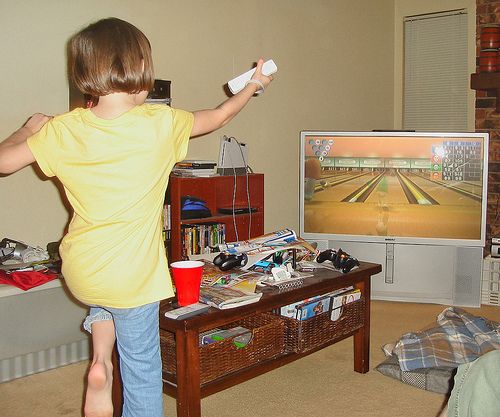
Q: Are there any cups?
A: Yes, there is a cup.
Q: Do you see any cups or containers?
A: Yes, there is a cup.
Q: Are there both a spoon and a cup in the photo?
A: No, there is a cup but no spoons.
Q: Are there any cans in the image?
A: No, there are no cans.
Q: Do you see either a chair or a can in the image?
A: No, there are no cans or chairs.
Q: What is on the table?
A: The cup is on the table.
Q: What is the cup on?
A: The cup is on the table.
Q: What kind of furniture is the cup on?
A: The cup is on the table.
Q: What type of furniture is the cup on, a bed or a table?
A: The cup is on a table.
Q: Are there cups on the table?
A: Yes, there is a cup on the table.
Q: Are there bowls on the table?
A: No, there is a cup on the table.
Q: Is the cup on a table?
A: Yes, the cup is on a table.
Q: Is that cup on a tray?
A: No, the cup is on a table.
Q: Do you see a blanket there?
A: Yes, there is a blanket.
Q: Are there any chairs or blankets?
A: Yes, there is a blanket.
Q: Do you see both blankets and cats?
A: No, there is a blanket but no cats.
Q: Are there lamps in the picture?
A: No, there are no lamps.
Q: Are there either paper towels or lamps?
A: No, there are no lamps or paper towels.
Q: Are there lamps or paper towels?
A: No, there are no lamps or paper towels.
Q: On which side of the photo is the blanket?
A: The blanket is on the right of the image.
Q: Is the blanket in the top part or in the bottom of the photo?
A: The blanket is in the bottom of the image.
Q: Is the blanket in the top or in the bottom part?
A: The blanket is in the bottom of the image.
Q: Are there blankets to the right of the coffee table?
A: Yes, there is a blanket to the right of the coffee table.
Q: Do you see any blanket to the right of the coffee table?
A: Yes, there is a blanket to the right of the coffee table.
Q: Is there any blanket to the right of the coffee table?
A: Yes, there is a blanket to the right of the coffee table.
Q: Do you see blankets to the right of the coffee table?
A: Yes, there is a blanket to the right of the coffee table.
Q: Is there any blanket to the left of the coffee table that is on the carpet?
A: No, the blanket is to the right of the coffee table.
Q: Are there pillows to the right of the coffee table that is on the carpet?
A: No, there is a blanket to the right of the coffee table.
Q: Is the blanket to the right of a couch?
A: No, the blanket is to the right of a coffee table.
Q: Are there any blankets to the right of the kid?
A: Yes, there is a blanket to the right of the kid.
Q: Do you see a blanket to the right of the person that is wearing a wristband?
A: Yes, there is a blanket to the right of the kid.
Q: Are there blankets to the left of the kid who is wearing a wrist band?
A: No, the blanket is to the right of the kid.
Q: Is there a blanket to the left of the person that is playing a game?
A: No, the blanket is to the right of the kid.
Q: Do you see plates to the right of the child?
A: No, there is a blanket to the right of the child.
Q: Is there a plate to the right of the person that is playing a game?
A: No, there is a blanket to the right of the child.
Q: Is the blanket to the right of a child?
A: Yes, the blanket is to the right of a child.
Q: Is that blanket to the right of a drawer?
A: No, the blanket is to the right of a child.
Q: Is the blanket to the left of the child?
A: No, the blanket is to the right of the child.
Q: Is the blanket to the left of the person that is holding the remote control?
A: No, the blanket is to the right of the child.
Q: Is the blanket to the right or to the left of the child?
A: The blanket is to the right of the child.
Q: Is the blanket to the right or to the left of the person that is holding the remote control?
A: The blanket is to the right of the child.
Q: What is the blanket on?
A: The blanket is on the carpet.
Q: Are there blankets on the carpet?
A: Yes, there is a blanket on the carpet.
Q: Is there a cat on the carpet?
A: No, there is a blanket on the carpet.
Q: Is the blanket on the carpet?
A: Yes, the blanket is on the carpet.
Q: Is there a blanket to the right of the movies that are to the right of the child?
A: Yes, there is a blanket to the right of the DVDs.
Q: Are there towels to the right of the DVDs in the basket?
A: No, there is a blanket to the right of the movies.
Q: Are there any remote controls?
A: Yes, there is a remote control.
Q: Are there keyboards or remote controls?
A: Yes, there is a remote control.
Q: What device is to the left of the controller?
A: The device is a remote control.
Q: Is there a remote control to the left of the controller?
A: Yes, there is a remote control to the left of the controller.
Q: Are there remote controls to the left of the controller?
A: Yes, there is a remote control to the left of the controller.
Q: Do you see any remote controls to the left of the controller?
A: Yes, there is a remote control to the left of the controller.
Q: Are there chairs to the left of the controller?
A: No, there is a remote control to the left of the controller.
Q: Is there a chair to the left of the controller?
A: No, there is a remote control to the left of the controller.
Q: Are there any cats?
A: No, there are no cats.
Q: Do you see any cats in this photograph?
A: No, there are no cats.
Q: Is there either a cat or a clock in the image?
A: No, there are no cats or clocks.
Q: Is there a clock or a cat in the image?
A: No, there are no cats or clocks.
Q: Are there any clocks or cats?
A: No, there are no cats or clocks.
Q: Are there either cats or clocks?
A: No, there are no cats or clocks.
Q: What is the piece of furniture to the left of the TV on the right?
A: The piece of furniture is a bookshelf.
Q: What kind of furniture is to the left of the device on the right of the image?
A: The piece of furniture is a bookshelf.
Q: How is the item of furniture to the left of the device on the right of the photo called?
A: The piece of furniture is a bookshelf.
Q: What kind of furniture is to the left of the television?
A: The piece of furniture is a bookshelf.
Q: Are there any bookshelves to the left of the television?
A: Yes, there is a bookshelf to the left of the television.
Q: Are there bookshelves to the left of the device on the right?
A: Yes, there is a bookshelf to the left of the television.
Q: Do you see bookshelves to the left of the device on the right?
A: Yes, there is a bookshelf to the left of the television.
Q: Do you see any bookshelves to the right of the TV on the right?
A: No, the bookshelf is to the left of the TV.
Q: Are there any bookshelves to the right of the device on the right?
A: No, the bookshelf is to the left of the TV.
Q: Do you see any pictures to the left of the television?
A: No, there is a bookshelf to the left of the television.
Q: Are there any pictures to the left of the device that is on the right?
A: No, there is a bookshelf to the left of the television.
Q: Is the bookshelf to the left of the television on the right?
A: Yes, the bookshelf is to the left of the TV.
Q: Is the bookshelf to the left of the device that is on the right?
A: Yes, the bookshelf is to the left of the TV.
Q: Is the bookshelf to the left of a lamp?
A: No, the bookshelf is to the left of the TV.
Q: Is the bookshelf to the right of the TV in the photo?
A: No, the bookshelf is to the left of the TV.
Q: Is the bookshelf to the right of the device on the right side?
A: No, the bookshelf is to the left of the TV.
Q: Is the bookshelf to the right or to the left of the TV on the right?
A: The bookshelf is to the left of the television.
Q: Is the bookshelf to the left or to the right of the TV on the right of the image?
A: The bookshelf is to the left of the television.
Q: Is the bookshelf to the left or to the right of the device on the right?
A: The bookshelf is to the left of the television.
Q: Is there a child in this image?
A: Yes, there is a child.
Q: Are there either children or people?
A: Yes, there is a child.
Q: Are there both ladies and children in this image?
A: No, there is a child but no ladies.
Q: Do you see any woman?
A: No, there are no women.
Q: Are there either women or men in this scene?
A: No, there are no women or men.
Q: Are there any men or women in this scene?
A: No, there are no women or men.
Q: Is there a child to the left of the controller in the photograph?
A: Yes, there is a child to the left of the controller.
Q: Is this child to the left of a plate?
A: No, the child is to the left of the controller.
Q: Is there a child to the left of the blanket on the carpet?
A: Yes, there is a child to the left of the blanket.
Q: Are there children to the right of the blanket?
A: No, the child is to the left of the blanket.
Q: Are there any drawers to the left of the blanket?
A: No, there is a child to the left of the blanket.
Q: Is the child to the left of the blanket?
A: Yes, the child is to the left of the blanket.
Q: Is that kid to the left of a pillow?
A: No, the kid is to the left of the blanket.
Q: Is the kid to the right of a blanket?
A: No, the kid is to the left of a blanket.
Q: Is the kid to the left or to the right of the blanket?
A: The kid is to the left of the blanket.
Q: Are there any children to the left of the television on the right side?
A: Yes, there is a child to the left of the TV.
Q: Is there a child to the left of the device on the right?
A: Yes, there is a child to the left of the TV.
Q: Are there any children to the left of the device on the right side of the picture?
A: Yes, there is a child to the left of the TV.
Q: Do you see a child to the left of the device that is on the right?
A: Yes, there is a child to the left of the TV.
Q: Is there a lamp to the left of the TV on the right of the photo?
A: No, there is a child to the left of the TV.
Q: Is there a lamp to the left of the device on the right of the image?
A: No, there is a child to the left of the TV.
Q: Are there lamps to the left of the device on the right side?
A: No, there is a child to the left of the TV.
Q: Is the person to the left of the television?
A: Yes, the child is to the left of the television.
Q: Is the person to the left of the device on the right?
A: Yes, the child is to the left of the television.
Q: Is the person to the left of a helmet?
A: No, the kid is to the left of the television.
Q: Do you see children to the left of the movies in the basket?
A: Yes, there is a child to the left of the DVDs.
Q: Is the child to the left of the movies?
A: Yes, the child is to the left of the movies.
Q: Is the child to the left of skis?
A: No, the child is to the left of the movies.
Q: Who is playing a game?
A: The child is playing a game.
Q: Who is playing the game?
A: The child is playing a game.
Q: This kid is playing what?
A: The kid is playing a game.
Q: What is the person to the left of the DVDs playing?
A: The kid is playing a game.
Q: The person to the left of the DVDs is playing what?
A: The kid is playing a game.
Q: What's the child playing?
A: The kid is playing a game.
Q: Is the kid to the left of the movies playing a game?
A: Yes, the kid is playing a game.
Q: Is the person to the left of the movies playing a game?
A: Yes, the kid is playing a game.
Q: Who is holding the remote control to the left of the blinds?
A: The kid is holding the remote.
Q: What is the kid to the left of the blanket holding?
A: The kid is holding the remote control.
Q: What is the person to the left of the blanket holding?
A: The kid is holding the remote control.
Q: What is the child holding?
A: The kid is holding the remote control.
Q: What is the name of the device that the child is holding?
A: The device is a remote control.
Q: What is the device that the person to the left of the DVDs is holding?
A: The device is a remote control.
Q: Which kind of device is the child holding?
A: The child is holding the remote.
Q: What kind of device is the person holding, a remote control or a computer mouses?
A: The child is holding a remote control.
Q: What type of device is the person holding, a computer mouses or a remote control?
A: The child is holding a remote control.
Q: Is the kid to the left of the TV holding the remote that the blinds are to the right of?
A: Yes, the child is holding the remote control.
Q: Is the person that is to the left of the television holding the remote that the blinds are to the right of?
A: Yes, the child is holding the remote control.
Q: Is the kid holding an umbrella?
A: No, the kid is holding the remote control.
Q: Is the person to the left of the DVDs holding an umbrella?
A: No, the kid is holding the remote control.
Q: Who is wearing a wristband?
A: The kid is wearing a wristband.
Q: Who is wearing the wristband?
A: The kid is wearing a wristband.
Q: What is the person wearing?
A: The child is wearing a wristband.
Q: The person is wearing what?
A: The child is wearing a wristband.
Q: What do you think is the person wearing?
A: The child is wearing a wristband.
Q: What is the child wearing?
A: The child is wearing a wristband.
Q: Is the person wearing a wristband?
A: Yes, the kid is wearing a wristband.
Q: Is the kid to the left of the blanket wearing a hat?
A: No, the kid is wearing a wristband.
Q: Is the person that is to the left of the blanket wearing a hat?
A: No, the kid is wearing a wristband.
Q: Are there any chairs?
A: No, there are no chairs.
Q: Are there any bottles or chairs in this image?
A: No, there are no chairs or bottles.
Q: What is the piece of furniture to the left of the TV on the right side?
A: The piece of furniture is a shelf.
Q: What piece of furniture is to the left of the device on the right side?
A: The piece of furniture is a shelf.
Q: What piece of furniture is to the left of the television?
A: The piece of furniture is a shelf.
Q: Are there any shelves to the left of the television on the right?
A: Yes, there is a shelf to the left of the television.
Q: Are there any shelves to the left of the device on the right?
A: Yes, there is a shelf to the left of the television.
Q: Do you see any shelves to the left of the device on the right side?
A: Yes, there is a shelf to the left of the television.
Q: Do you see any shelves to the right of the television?
A: No, the shelf is to the left of the television.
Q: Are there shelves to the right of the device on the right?
A: No, the shelf is to the left of the television.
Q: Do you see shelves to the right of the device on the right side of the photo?
A: No, the shelf is to the left of the television.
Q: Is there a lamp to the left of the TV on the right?
A: No, there is a shelf to the left of the television.